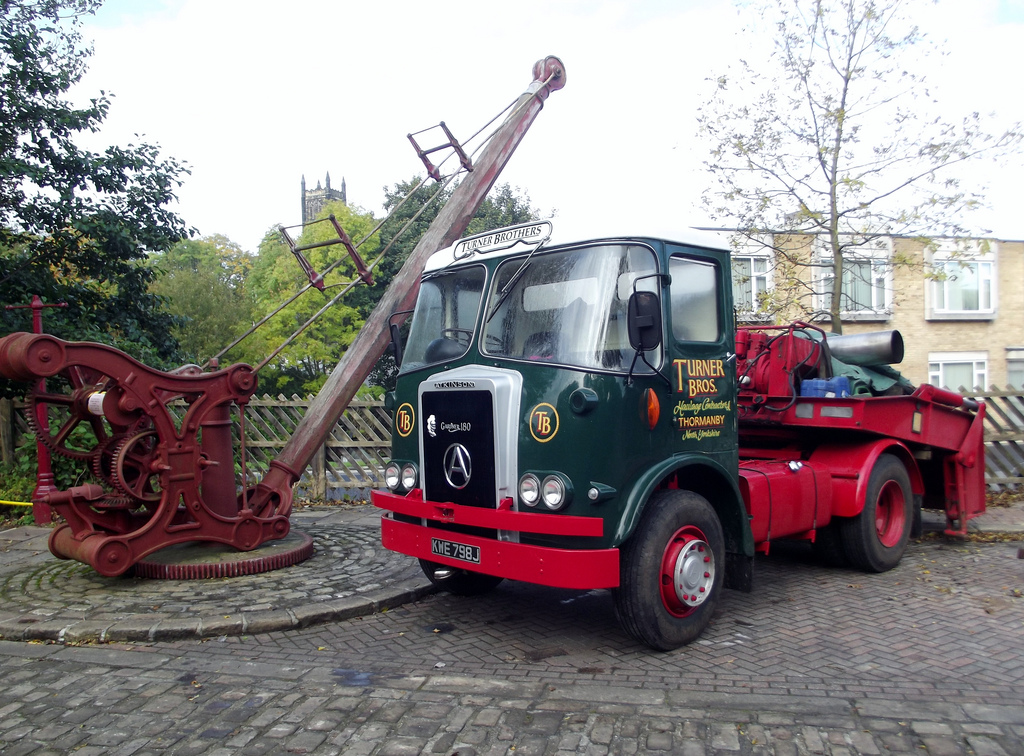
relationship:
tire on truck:
[627, 469, 740, 666] [362, 214, 993, 662]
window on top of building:
[807, 236, 909, 321] [677, 63, 993, 405]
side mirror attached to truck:
[621, 268, 686, 398] [362, 214, 993, 662]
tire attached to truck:
[611, 488, 724, 651] [362, 214, 993, 662]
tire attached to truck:
[844, 452, 915, 572] [362, 214, 993, 662]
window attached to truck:
[662, 243, 734, 354] [362, 214, 993, 662]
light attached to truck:
[539, 471, 572, 513] [362, 214, 993, 662]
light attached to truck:
[516, 469, 542, 509] [362, 214, 993, 662]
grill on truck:
[423, 375, 499, 516] [362, 214, 993, 662]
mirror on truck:
[626, 278, 668, 363] [384, 213, 981, 637]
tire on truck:
[848, 449, 922, 566] [384, 213, 981, 637]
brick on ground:
[773, 611, 830, 657] [15, 446, 1016, 745]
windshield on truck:
[395, 246, 653, 387] [384, 213, 981, 637]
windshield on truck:
[384, 261, 478, 363] [384, 213, 981, 637]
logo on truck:
[434, 438, 480, 491] [362, 214, 993, 662]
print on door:
[671, 353, 726, 401] [656, 241, 745, 486]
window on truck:
[669, 252, 727, 342] [362, 214, 993, 662]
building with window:
[636, 183, 1023, 445] [798, 228, 891, 319]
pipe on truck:
[813, 332, 909, 369] [369, 221, 987, 653]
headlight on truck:
[375, 459, 412, 492] [369, 221, 987, 653]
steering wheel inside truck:
[437, 315, 507, 361] [369, 221, 987, 653]